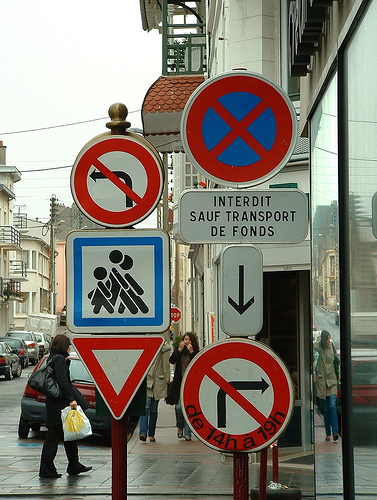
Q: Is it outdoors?
A: Yes, it is outdoors.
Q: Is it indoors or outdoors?
A: It is outdoors.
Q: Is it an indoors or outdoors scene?
A: It is outdoors.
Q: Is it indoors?
A: No, it is outdoors.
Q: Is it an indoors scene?
A: No, it is outdoors.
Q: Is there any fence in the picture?
A: No, there are no fences.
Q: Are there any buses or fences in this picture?
A: No, there are no fences or buses.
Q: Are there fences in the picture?
A: No, there are no fences.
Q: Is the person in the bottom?
A: Yes, the person is in the bottom of the image.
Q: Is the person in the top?
A: No, the person is in the bottom of the image.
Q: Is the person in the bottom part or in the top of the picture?
A: The person is in the bottom of the image.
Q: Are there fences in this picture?
A: No, there are no fences.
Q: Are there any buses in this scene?
A: No, there are no buses.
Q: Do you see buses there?
A: No, there are no buses.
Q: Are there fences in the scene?
A: No, there are no fences.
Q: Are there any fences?
A: No, there are no fences.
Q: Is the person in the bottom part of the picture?
A: Yes, the person is in the bottom of the image.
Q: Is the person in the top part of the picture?
A: No, the person is in the bottom of the image.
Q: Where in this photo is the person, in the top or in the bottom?
A: The person is in the bottom of the image.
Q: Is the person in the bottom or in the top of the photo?
A: The person is in the bottom of the image.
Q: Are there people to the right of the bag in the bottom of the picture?
A: Yes, there is a person to the right of the bag.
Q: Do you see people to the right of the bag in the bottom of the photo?
A: Yes, there is a person to the right of the bag.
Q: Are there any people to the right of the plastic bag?
A: Yes, there is a person to the right of the bag.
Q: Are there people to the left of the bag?
A: No, the person is to the right of the bag.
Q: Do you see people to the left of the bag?
A: No, the person is to the right of the bag.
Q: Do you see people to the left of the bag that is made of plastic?
A: No, the person is to the right of the bag.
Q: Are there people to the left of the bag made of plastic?
A: No, the person is to the right of the bag.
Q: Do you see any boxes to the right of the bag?
A: No, there is a person to the right of the bag.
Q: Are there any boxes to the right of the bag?
A: No, there is a person to the right of the bag.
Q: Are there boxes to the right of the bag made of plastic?
A: No, there is a person to the right of the bag.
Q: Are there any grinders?
A: No, there are no grinders.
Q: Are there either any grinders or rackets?
A: No, there are no grinders or rackets.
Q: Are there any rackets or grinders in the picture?
A: No, there are no grinders or rackets.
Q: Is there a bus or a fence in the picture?
A: No, there are no fences or buses.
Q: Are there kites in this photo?
A: No, there are no kites.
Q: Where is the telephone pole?
A: The telephone pole is on the street.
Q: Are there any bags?
A: Yes, there is a bag.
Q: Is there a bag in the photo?
A: Yes, there is a bag.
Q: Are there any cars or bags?
A: Yes, there is a bag.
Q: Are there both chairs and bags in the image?
A: No, there is a bag but no chairs.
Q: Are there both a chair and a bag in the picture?
A: No, there is a bag but no chairs.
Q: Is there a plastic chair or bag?
A: Yes, there is a plastic bag.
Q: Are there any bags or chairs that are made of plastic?
A: Yes, the bag is made of plastic.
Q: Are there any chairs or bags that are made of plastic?
A: Yes, the bag is made of plastic.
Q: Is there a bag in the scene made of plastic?
A: Yes, there is a bag that is made of plastic.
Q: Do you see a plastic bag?
A: Yes, there is a bag that is made of plastic.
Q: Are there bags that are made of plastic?
A: Yes, there is a bag that is made of plastic.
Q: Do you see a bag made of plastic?
A: Yes, there is a bag that is made of plastic.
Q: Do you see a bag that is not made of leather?
A: Yes, there is a bag that is made of plastic.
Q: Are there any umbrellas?
A: No, there are no umbrellas.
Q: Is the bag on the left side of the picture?
A: Yes, the bag is on the left of the image.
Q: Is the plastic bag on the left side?
A: Yes, the bag is on the left of the image.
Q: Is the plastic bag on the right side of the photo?
A: No, the bag is on the left of the image.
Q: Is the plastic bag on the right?
A: No, the bag is on the left of the image.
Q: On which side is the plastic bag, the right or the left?
A: The bag is on the left of the image.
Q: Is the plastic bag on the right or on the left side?
A: The bag is on the left of the image.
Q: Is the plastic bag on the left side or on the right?
A: The bag is on the left of the image.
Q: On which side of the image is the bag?
A: The bag is on the left of the image.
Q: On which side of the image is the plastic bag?
A: The bag is on the left of the image.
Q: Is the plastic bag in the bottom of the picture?
A: Yes, the bag is in the bottom of the image.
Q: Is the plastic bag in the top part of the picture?
A: No, the bag is in the bottom of the image.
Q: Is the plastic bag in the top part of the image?
A: No, the bag is in the bottom of the image.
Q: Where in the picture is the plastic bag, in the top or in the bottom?
A: The bag is in the bottom of the image.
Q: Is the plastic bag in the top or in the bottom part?
A: The bag is in the bottom of the image.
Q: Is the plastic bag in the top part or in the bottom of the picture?
A: The bag is in the bottom of the image.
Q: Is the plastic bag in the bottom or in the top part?
A: The bag is in the bottom of the image.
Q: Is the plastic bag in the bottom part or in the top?
A: The bag is in the bottom of the image.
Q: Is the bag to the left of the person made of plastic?
A: Yes, the bag is made of plastic.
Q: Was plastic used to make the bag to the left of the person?
A: Yes, the bag is made of plastic.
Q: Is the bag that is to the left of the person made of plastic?
A: Yes, the bag is made of plastic.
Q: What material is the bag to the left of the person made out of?
A: The bag is made of plastic.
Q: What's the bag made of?
A: The bag is made of plastic.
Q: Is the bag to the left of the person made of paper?
A: No, the bag is made of plastic.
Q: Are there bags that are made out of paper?
A: No, there is a bag but it is made of plastic.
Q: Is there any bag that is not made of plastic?
A: No, there is a bag but it is made of plastic.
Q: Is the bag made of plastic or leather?
A: The bag is made of plastic.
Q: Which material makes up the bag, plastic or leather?
A: The bag is made of plastic.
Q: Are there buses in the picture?
A: No, there are no buses.